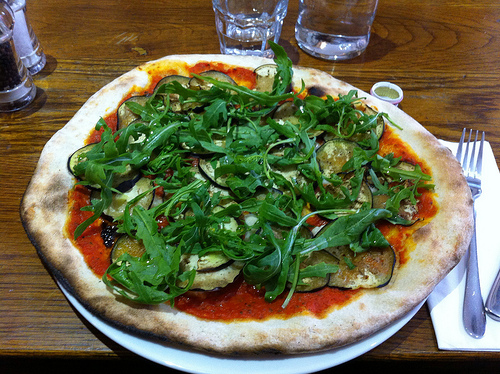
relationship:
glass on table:
[306, 0, 364, 78] [1, 3, 496, 361]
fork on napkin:
[452, 127, 494, 337] [428, 134, 498, 346]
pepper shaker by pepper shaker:
[0, 0, 45, 114] [0, 0, 38, 114]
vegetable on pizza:
[106, 64, 411, 294] [19, 55, 473, 352]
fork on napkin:
[446, 116, 491, 345] [430, 129, 497, 364]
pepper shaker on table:
[0, 0, 45, 114] [1, 3, 496, 361]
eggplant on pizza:
[177, 257, 245, 296] [72, 79, 421, 307]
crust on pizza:
[20, 52, 474, 359] [39, 28, 466, 347]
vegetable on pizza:
[66, 40, 412, 308] [22, 38, 482, 368]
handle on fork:
[470, 245, 496, 315] [452, 127, 494, 337]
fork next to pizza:
[443, 122, 493, 347] [160, 113, 315, 246]